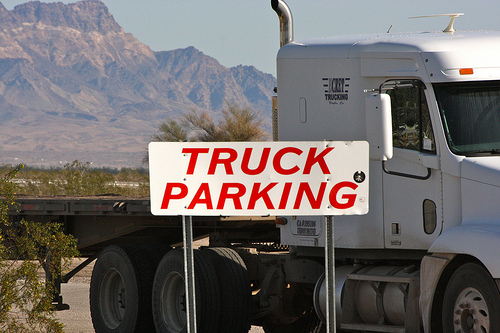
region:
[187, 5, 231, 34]
this is the sky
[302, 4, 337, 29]
the sky is blue in color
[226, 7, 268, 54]
the sky has some clouds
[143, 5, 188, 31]
the clouds are white in color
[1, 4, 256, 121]
this is a mountain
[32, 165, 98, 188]
this is the grass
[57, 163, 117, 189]
the grass is green in color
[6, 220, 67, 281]
the leaves are green in color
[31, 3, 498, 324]
this is a truck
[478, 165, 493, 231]
the truck is white in color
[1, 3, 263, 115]
grey mountain peaks in the distance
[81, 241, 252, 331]
black semi truck tires and wheels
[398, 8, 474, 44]
wifi antenna on top of semi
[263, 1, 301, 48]
chrome exhaust stack on semi truck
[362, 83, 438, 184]
side mirror on semi truck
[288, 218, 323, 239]
department of transportation numbers on side of semi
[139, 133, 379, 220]
red and white sign directing semi trucks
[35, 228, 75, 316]
trailer jack under trailer of semi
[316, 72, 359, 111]
company name of semi truck company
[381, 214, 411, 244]
door handle on side of semi truck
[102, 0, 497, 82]
clear blue daytime sky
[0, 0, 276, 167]
hazy mountains in distance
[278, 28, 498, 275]
cab of white truck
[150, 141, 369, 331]
sign on two poles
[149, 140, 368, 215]
red words on white sign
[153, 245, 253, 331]
two tires side by side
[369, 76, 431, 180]
back of mirror on two poles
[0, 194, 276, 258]
flat top of truck bed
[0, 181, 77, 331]
green leaves of bush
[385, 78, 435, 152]
truck window with reflection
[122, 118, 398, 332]
a red and white sign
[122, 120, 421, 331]
a truck parking sign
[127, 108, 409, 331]
the sign is white with red letters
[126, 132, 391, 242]
the words on the sign are red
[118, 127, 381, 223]
all the letters are capitalized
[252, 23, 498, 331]
the tuck is white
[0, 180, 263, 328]
a trailer attached to the truck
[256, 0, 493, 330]
a big white truck cab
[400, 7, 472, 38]
an antenna on top of the truck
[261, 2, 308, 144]
the truck cab's exhaust pipe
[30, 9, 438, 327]
This is a rest stop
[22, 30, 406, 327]
This is in the desert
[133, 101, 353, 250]
The sign is red and white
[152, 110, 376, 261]
The writing is red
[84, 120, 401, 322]
the sign says Truck Parking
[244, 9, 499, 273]
This is a semi truck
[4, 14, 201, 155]
These are mountains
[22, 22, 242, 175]
The mountains are brown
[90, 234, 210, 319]
These tires are big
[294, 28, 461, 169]
The semi truck is white